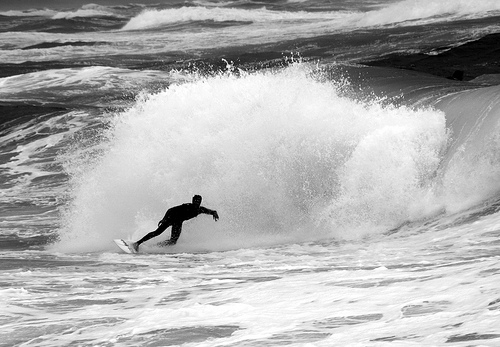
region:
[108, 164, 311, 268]
Man on a surfboard.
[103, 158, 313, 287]
Man in the water.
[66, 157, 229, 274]
Man in a wetsuit.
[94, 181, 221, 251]
Man on a white surfboard.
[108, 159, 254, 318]
Man in a black wet suit.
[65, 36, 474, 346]
Big wave in the water.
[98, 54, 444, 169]
Spray on the water.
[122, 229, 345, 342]
Ripples in the water.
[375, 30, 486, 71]
Rocks in the background.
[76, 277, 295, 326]
White caps on the waves.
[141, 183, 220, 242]
this is a man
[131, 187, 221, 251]
the man is sea surfing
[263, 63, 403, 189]
waves are beside the man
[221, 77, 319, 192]
the water is splashy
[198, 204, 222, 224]
this is the hand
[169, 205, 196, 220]
the costume is black in color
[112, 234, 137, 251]
this is a surf bord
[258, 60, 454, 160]
the waves are strong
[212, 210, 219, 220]
the fingers are bent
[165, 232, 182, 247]
this is the knee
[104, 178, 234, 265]
He is surfing.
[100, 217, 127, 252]
His board is white.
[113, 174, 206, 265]
He is leaning.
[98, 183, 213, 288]
He is balancing.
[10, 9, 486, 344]
The water is rough.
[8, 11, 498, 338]
The man is in the ocean.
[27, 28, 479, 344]
The wave is splashing.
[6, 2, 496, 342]
He is in the ocean.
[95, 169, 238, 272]
The man is wet.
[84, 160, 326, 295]
a person is surfing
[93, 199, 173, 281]
the surfboard is white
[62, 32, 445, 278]
the waves are in motion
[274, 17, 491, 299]
the waves are rolling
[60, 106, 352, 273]
the water is splashing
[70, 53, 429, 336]
the wave is white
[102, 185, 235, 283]
the person is leaning right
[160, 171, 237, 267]
the person`s arm is up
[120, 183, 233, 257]
the person is wearing all black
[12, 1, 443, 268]
the ocean is rough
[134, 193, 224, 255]
Water skier dressed in black.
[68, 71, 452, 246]
Splashing water surrounding a water skier.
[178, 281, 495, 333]
White foam water covering splashing water.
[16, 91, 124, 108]
Small waves in rustling water.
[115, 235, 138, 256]
A white surfboard leaning to the side.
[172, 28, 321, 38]
Bubbles boucing quickly in the water.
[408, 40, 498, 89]
Black sink hole in the ocean.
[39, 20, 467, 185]
Swirling water splashing backwards and forwards.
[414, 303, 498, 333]
Settled waters shown in the right corner.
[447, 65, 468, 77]
Second surfer has fallen in the water.